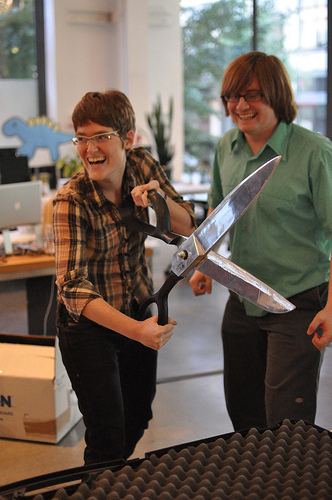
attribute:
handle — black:
[150, 271, 178, 295]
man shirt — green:
[204, 49, 330, 317]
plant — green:
[139, 89, 190, 199]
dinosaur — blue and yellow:
[167, 229, 195, 273]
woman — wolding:
[203, 74, 328, 224]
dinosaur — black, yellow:
[2, 114, 77, 163]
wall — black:
[2, 1, 181, 199]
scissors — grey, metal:
[158, 189, 293, 482]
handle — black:
[101, 160, 194, 236]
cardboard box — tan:
[0, 321, 108, 451]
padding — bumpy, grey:
[137, 443, 330, 493]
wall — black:
[55, 35, 116, 81]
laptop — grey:
[1, 181, 59, 235]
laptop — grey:
[0, 178, 45, 228]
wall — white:
[52, 0, 184, 185]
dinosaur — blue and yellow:
[4, 104, 71, 174]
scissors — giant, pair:
[107, 155, 295, 315]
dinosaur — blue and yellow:
[1, 109, 83, 166]